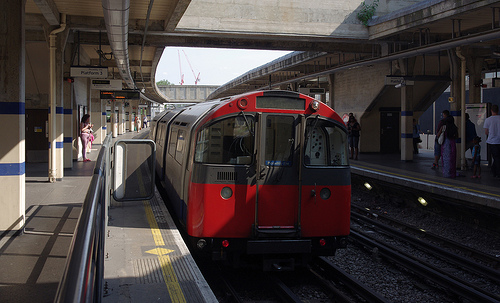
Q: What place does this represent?
A: It represents the station.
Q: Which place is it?
A: It is a station.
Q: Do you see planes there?
A: No, there are no planes.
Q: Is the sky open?
A: Yes, the sky is open.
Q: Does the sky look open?
A: Yes, the sky is open.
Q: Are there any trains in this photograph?
A: Yes, there is a train.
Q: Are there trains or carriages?
A: Yes, there is a train.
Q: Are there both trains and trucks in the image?
A: No, there is a train but no trucks.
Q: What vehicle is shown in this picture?
A: The vehicle is a train.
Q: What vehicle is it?
A: The vehicle is a train.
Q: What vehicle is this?
A: This is a train.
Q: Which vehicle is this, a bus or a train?
A: This is a train.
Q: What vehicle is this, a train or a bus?
A: This is a train.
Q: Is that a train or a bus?
A: That is a train.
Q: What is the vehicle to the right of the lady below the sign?
A: The vehicle is a train.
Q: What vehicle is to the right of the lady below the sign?
A: The vehicle is a train.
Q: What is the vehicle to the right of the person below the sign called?
A: The vehicle is a train.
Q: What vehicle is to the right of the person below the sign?
A: The vehicle is a train.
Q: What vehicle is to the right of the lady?
A: The vehicle is a train.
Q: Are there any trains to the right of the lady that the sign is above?
A: Yes, there is a train to the right of the lady.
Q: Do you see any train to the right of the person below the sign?
A: Yes, there is a train to the right of the lady.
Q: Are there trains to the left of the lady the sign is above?
A: No, the train is to the right of the lady.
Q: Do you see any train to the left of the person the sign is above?
A: No, the train is to the right of the lady.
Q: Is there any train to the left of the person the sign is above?
A: No, the train is to the right of the lady.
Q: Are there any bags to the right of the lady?
A: No, there is a train to the right of the lady.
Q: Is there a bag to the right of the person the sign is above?
A: No, there is a train to the right of the lady.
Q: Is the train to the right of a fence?
A: No, the train is to the right of the lady.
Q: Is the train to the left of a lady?
A: No, the train is to the right of a lady.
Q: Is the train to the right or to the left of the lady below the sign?
A: The train is to the right of the lady.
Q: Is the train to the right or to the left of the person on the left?
A: The train is to the right of the lady.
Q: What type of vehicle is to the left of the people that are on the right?
A: The vehicle is a train.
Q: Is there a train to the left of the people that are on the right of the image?
A: Yes, there is a train to the left of the people.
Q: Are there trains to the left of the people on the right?
A: Yes, there is a train to the left of the people.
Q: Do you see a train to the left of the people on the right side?
A: Yes, there is a train to the left of the people.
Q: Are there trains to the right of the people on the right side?
A: No, the train is to the left of the people.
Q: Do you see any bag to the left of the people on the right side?
A: No, there is a train to the left of the people.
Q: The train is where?
A: The train is at the station.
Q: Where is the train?
A: The train is at the station.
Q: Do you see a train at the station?
A: Yes, there is a train at the station.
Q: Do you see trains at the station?
A: Yes, there is a train at the station.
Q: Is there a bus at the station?
A: No, there is a train at the station.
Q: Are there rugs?
A: No, there are no rugs.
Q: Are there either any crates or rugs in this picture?
A: No, there are no rugs or crates.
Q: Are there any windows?
A: Yes, there are windows.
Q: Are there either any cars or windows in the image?
A: Yes, there are windows.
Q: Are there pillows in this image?
A: No, there are no pillows.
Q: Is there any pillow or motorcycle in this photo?
A: No, there are no pillows or motorcycles.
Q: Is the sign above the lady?
A: Yes, the sign is above the lady.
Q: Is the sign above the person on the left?
A: Yes, the sign is above the lady.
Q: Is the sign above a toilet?
A: No, the sign is above the lady.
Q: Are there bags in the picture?
A: No, there are no bags.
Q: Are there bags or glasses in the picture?
A: No, there are no bags or glasses.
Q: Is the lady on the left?
A: Yes, the lady is on the left of the image.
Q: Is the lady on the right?
A: No, the lady is on the left of the image.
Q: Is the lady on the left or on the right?
A: The lady is on the left of the image.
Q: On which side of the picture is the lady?
A: The lady is on the left of the image.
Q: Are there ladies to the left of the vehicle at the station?
A: Yes, there is a lady to the left of the train.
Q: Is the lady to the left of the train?
A: Yes, the lady is to the left of the train.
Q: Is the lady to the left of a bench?
A: No, the lady is to the left of the train.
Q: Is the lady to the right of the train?
A: No, the lady is to the left of the train.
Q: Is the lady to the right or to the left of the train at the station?
A: The lady is to the left of the train.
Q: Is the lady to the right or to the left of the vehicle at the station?
A: The lady is to the left of the train.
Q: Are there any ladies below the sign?
A: Yes, there is a lady below the sign.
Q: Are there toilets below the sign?
A: No, there is a lady below the sign.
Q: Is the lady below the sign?
A: Yes, the lady is below the sign.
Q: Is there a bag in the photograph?
A: No, there are no bags.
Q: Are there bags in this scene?
A: No, there are no bags.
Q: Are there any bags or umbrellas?
A: No, there are no bags or umbrellas.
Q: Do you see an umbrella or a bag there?
A: No, there are no bags or umbrellas.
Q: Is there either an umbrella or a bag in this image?
A: No, there are no bags or umbrellas.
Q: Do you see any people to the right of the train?
A: Yes, there are people to the right of the train.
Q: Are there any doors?
A: Yes, there is a door.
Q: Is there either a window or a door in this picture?
A: Yes, there is a door.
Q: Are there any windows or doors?
A: Yes, there is a door.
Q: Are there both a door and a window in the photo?
A: Yes, there are both a door and a window.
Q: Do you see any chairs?
A: No, there are no chairs.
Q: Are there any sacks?
A: No, there are no sacks.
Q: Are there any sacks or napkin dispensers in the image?
A: No, there are no sacks or napkin dispensers.